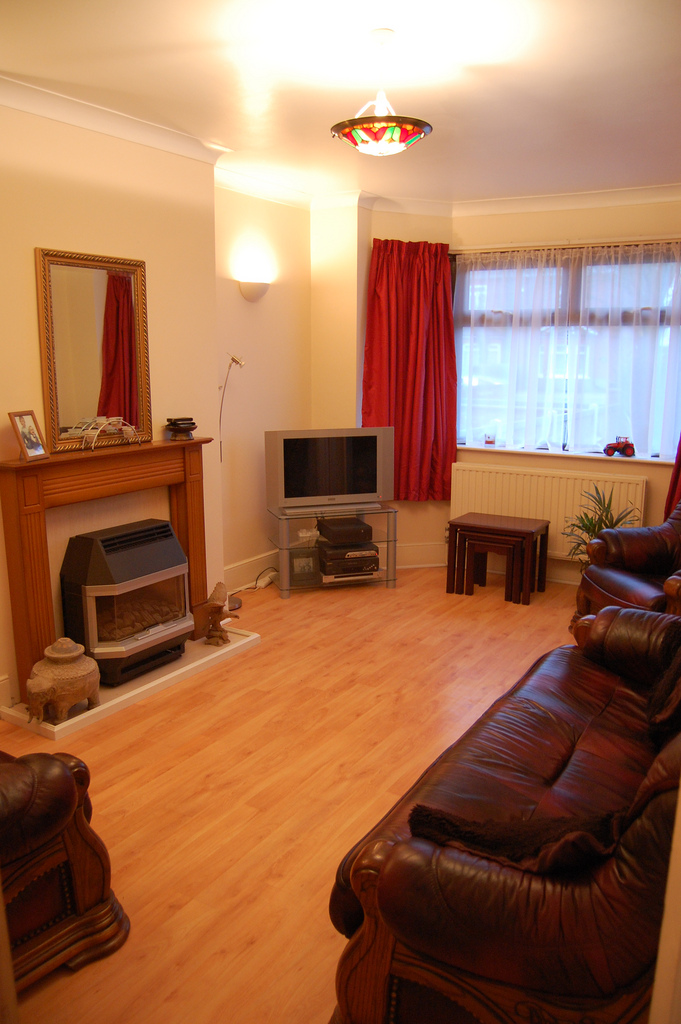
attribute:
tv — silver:
[260, 424, 398, 509]